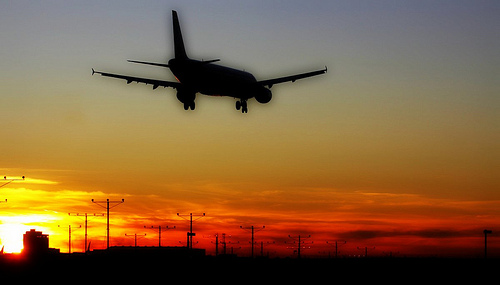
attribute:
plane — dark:
[89, 9, 328, 114]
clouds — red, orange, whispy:
[12, 173, 488, 251]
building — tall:
[22, 228, 50, 258]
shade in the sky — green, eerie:
[346, 224, 466, 242]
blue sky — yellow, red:
[1, 1, 496, 77]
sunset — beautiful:
[5, 174, 490, 255]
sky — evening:
[13, 18, 495, 209]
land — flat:
[20, 245, 490, 282]